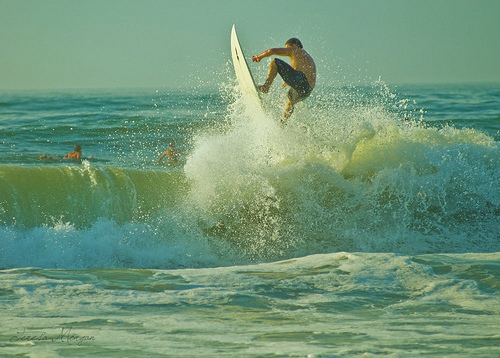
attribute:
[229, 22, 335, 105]
man — surfing, white, sufring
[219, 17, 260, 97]
board — white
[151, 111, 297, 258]
water — blue, white, calm, green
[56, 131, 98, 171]
person — swimming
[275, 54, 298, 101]
shorts — black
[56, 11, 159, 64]
sky — blue